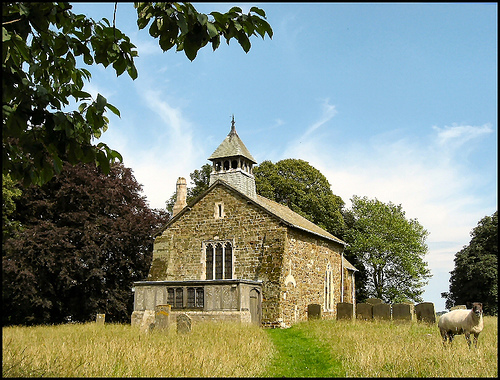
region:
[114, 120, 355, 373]
building in the field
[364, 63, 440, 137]
blue sky above the clouds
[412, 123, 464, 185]
white clouds in the sky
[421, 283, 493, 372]
animal on the ground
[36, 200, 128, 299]
tree next to the building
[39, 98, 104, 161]
leaves on the tree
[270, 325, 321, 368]
green grass path in the photo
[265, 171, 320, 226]
roof of the building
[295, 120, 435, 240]
trees behind the building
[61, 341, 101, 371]
grass next to the path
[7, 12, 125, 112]
The tree is leafy.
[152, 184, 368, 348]
The building is brick.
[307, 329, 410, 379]
The grass is dying.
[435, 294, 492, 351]
The sheep is white.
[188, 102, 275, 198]
The steeple is short.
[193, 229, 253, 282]
The windows are narrow.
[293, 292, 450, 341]
The tomb stones are lined up.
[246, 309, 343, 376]
The path is made of grass.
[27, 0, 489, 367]
The sun is shining.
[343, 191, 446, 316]
The tree is tall.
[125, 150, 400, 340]
An old church sits in the field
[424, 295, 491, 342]
Lamb stands in front of building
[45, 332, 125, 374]
Tall grass in the field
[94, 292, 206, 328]
Gravestones in front of church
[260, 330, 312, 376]
Path made of green grass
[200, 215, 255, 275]
windows on front of church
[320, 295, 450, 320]
Old gravestones in field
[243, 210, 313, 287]
Building is made of stone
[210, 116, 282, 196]
Steeple on top of church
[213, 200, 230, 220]
Small window on building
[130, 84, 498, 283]
these are white clouds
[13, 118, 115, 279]
these are green leaves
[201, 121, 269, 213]
this is a tower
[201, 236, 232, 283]
this is a window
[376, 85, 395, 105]
this is the color blue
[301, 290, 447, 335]
these are tomb stones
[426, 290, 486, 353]
this is a goat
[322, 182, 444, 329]
this is a tree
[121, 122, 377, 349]
this is a house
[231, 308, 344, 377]
this is a pathway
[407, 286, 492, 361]
One sheep standing alone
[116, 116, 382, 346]
An old church building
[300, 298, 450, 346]
A row of headstones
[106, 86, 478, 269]
White wispy clouds in the sky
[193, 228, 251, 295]
Three arched windows on building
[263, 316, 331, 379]
A green grass pathway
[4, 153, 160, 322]
A tree with red leaves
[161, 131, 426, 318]
Trees behind the building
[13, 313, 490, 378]
Yellow grass with green pathway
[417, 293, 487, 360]
A white sheep with black head